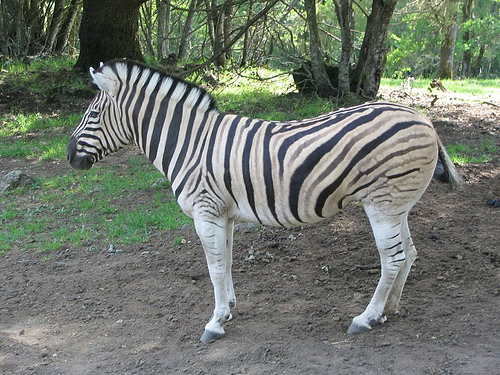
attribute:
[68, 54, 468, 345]
zebra — black, white, standing, looking, striped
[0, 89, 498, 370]
dirt — black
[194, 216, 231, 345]
leg — white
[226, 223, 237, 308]
leg — white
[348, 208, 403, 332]
leg — white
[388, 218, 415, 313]
leg — white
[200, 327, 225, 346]
hoof — black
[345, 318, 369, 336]
hoof — black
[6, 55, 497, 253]
grass — green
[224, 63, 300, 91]
sun — shining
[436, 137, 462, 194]
tail — short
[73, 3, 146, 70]
trunk — dark, large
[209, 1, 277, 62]
trunk — large, dark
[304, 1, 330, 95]
trunk — dark, large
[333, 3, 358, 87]
trunk — dark, large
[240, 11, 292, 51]
branches — dry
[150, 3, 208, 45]
branches — dry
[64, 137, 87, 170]
nose — black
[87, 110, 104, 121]
eye — open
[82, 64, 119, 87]
ear — wide apart